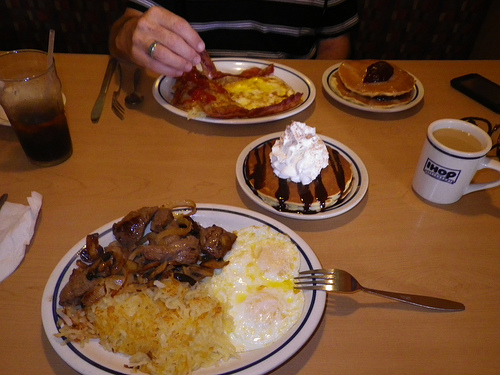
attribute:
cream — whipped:
[272, 127, 344, 188]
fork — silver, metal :
[296, 262, 472, 318]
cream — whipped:
[271, 120, 328, 182]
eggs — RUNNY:
[222, 219, 304, 348]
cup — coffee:
[436, 127, 484, 212]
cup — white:
[389, 114, 493, 179]